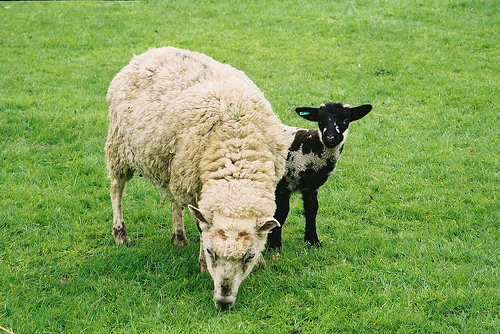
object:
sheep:
[100, 44, 288, 316]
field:
[0, 0, 500, 333]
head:
[183, 201, 279, 312]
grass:
[1, 0, 499, 333]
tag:
[297, 110, 310, 118]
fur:
[164, 76, 270, 172]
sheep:
[263, 103, 373, 254]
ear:
[188, 204, 215, 227]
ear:
[255, 218, 284, 236]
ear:
[294, 106, 322, 122]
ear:
[346, 104, 375, 120]